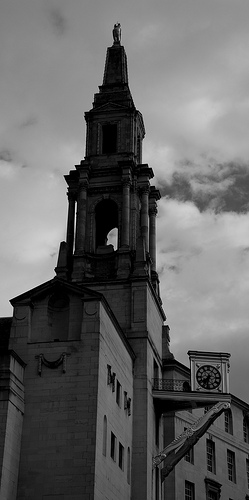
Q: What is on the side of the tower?
A: A clock.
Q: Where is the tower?
A: On the building.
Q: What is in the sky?
A: Clouds.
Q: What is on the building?
A: Windows.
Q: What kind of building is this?
A: Tall.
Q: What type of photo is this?
A: Black and white.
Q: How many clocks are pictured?
A: One.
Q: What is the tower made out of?
A: Stone.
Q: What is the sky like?
A: Cloudy.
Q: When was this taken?
A: Daytime.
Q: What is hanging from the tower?
A: A clock.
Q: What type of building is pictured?
A: A tower.